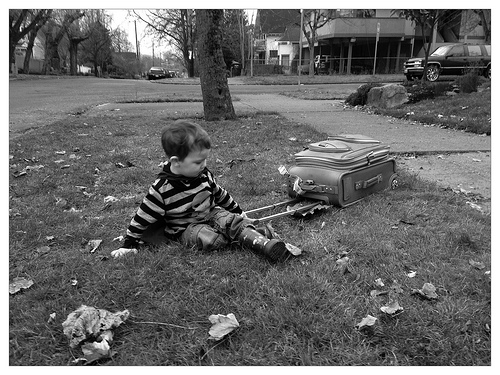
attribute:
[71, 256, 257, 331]
grass — little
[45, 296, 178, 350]
leaf — big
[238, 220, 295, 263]
boots — rain boots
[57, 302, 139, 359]
leaves — large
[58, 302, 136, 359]
leaf — big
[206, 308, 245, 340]
leaf — big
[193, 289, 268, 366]
leaf — big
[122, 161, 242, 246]
shirt — striped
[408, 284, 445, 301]
leaf — big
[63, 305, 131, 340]
leaf — big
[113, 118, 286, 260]
boy — little, young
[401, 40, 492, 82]
suv — black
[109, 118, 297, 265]
boy — young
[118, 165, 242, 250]
shirt — striped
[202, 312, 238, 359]
leaf — dead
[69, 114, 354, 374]
patch — grassy 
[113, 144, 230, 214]
shirt — striped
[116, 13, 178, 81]
pole — wood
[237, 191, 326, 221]
handle — pulled up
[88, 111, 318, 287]
boy — young